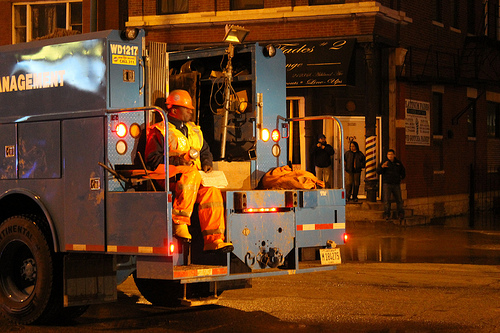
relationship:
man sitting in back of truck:
[144, 84, 236, 255] [0, 33, 350, 313]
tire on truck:
[0, 212, 89, 327] [0, 33, 350, 313]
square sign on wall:
[404, 100, 434, 147] [405, 144, 430, 198]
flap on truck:
[58, 261, 111, 308] [8, 37, 348, 273]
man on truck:
[144, 89, 234, 257] [0, 33, 350, 313]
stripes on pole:
[366, 135, 376, 181] [363, 43, 378, 200]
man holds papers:
[144, 89, 234, 257] [198, 170, 227, 187]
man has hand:
[144, 89, 234, 257] [197, 162, 211, 172]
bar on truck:
[105, 101, 191, 161] [52, 122, 125, 230]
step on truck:
[179, 274, 224, 309] [0, 33, 350, 313]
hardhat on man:
[167, 89, 194, 111] [144, 84, 236, 255]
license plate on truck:
[318, 244, 344, 266] [0, 33, 350, 313]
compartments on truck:
[55, 110, 107, 251] [0, 33, 350, 313]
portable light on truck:
[220, 23, 249, 158] [0, 33, 350, 313]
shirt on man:
[142, 119, 216, 174] [144, 84, 236, 255]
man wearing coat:
[374, 136, 423, 251] [379, 157, 406, 171]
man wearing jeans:
[374, 150, 407, 222] [375, 176, 406, 221]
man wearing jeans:
[374, 150, 407, 222] [342, 171, 363, 203]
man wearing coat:
[374, 150, 407, 222] [321, 153, 373, 171]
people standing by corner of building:
[301, 129, 418, 235] [1, 1, 495, 247]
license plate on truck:
[320, 248, 342, 266] [71, 60, 130, 217]